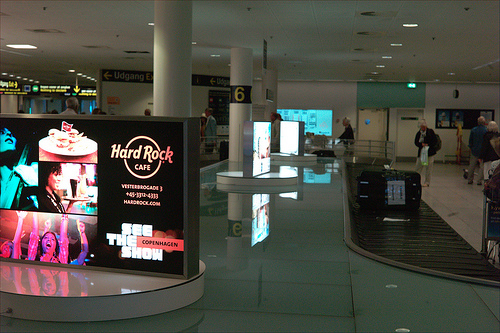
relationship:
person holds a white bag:
[414, 118, 444, 181] [424, 144, 430, 158]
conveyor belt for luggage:
[349, 161, 499, 285] [356, 170, 424, 216]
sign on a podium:
[244, 122, 277, 176] [215, 162, 304, 193]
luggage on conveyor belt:
[356, 170, 424, 216] [349, 161, 499, 285]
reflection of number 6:
[225, 217, 247, 240] [234, 84, 248, 102]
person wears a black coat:
[414, 118, 444, 181] [414, 129, 436, 154]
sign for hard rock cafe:
[1, 118, 190, 279] [106, 144, 178, 176]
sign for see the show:
[1, 118, 190, 279] [106, 221, 178, 261]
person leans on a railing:
[341, 116, 357, 157] [339, 138, 398, 165]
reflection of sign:
[250, 194, 272, 247] [244, 122, 277, 176]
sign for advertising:
[244, 122, 277, 176] [256, 120, 276, 173]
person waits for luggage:
[414, 118, 444, 181] [356, 170, 424, 216]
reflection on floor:
[250, 194, 272, 247] [173, 141, 496, 328]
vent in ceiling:
[124, 49, 152, 58] [3, 1, 499, 82]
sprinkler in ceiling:
[459, 2, 473, 19] [3, 1, 499, 82]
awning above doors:
[359, 86, 428, 110] [360, 110, 420, 160]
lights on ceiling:
[375, 15, 422, 79] [3, 1, 499, 82]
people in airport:
[201, 105, 227, 159] [5, 2, 498, 331]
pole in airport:
[151, 1, 194, 124] [5, 2, 498, 331]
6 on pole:
[234, 84, 248, 102] [151, 1, 194, 124]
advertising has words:
[256, 120, 276, 173] [244, 122, 277, 176]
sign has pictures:
[1, 118, 190, 279] [1, 123, 97, 263]